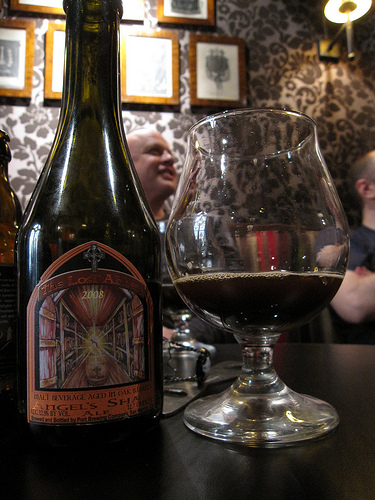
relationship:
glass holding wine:
[167, 102, 346, 438] [187, 273, 321, 322]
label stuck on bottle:
[25, 245, 157, 421] [12, 3, 165, 450]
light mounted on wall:
[319, 0, 375, 30] [3, 2, 374, 105]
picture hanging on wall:
[192, 36, 245, 107] [3, 2, 374, 105]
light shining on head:
[138, 129, 152, 134] [130, 130, 173, 200]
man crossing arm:
[337, 154, 374, 331] [340, 279, 372, 316]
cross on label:
[86, 245, 106, 266] [25, 245, 157, 421]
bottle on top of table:
[12, 3, 165, 450] [102, 440, 235, 487]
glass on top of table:
[167, 102, 346, 438] [102, 440, 235, 487]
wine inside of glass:
[187, 273, 321, 322] [167, 102, 346, 438]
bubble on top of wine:
[184, 274, 346, 281] [187, 273, 321, 322]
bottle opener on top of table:
[167, 346, 233, 394] [102, 440, 235, 487]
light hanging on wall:
[319, 0, 375, 30] [3, 2, 374, 105]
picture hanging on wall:
[124, 31, 184, 106] [3, 2, 374, 105]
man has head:
[337, 154, 374, 331] [130, 130, 173, 200]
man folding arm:
[337, 154, 374, 331] [340, 279, 372, 316]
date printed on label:
[82, 291, 103, 299] [25, 245, 157, 421]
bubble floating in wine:
[184, 274, 346, 281] [187, 273, 321, 322]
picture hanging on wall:
[3, 21, 35, 98] [3, 2, 374, 105]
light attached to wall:
[319, 0, 375, 30] [3, 2, 374, 105]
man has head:
[139, 133, 175, 223] [130, 130, 173, 200]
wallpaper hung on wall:
[256, 16, 309, 95] [3, 2, 374, 105]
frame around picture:
[165, 18, 212, 26] [165, 1, 215, 25]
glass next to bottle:
[167, 102, 346, 438] [12, 3, 165, 450]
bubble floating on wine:
[184, 274, 346, 281] [187, 273, 321, 322]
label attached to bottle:
[25, 245, 157, 421] [12, 3, 165, 450]